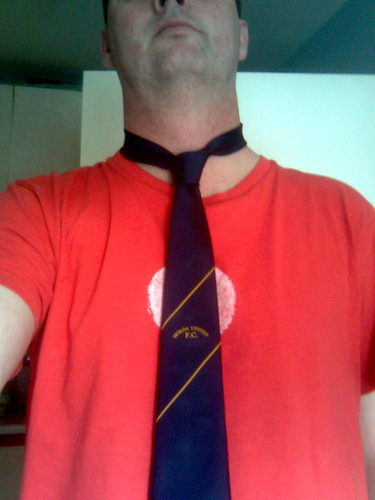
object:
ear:
[237, 19, 249, 61]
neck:
[117, 74, 253, 181]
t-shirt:
[0, 140, 375, 488]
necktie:
[119, 117, 247, 495]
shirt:
[0, 145, 375, 494]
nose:
[150, 0, 188, 10]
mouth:
[147, 12, 203, 41]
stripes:
[153, 265, 224, 423]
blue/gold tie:
[119, 122, 247, 500]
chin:
[132, 41, 230, 85]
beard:
[133, 52, 234, 99]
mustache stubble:
[139, 6, 211, 58]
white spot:
[145, 259, 237, 331]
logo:
[172, 324, 209, 340]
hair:
[133, 41, 221, 107]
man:
[0, 0, 369, 488]